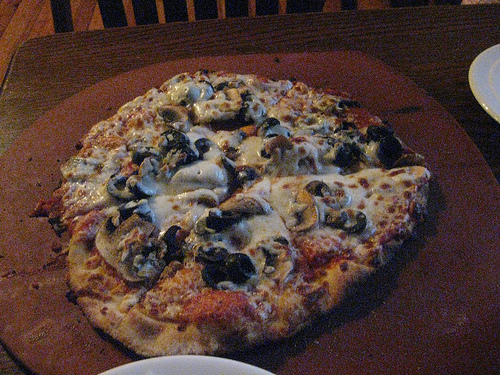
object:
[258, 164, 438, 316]
slice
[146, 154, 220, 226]
cheese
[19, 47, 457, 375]
pizza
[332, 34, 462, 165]
stone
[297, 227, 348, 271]
sauce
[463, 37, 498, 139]
plate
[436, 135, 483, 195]
table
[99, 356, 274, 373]
plate edge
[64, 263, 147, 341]
crust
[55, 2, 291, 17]
wooden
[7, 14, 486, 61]
brown table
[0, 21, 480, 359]
board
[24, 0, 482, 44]
chair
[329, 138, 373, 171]
olive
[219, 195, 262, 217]
murshrooms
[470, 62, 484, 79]
part